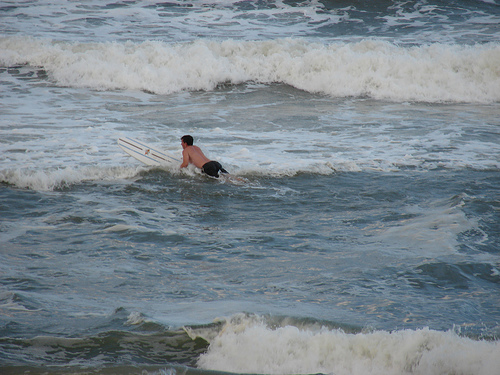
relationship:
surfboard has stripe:
[115, 135, 184, 166] [120, 144, 193, 175]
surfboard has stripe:
[115, 135, 184, 166] [116, 136, 183, 166]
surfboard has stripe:
[115, 135, 184, 166] [126, 131, 179, 161]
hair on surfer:
[175, 128, 196, 147] [178, 134, 231, 179]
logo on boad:
[146, 147, 151, 159] [114, 138, 183, 168]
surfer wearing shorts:
[178, 134, 231, 179] [203, 156, 226, 176]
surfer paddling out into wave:
[176, 132, 245, 191] [7, 297, 498, 374]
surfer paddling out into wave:
[176, 132, 245, 191] [4, 147, 499, 216]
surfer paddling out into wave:
[176, 132, 245, 191] [1, 21, 498, 116]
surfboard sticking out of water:
[115, 135, 184, 166] [2, 1, 499, 373]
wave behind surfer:
[55, 21, 484, 138] [166, 133, 269, 229]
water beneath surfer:
[2, 1, 499, 373] [180, 134, 247, 184]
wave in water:
[0, 145, 499, 199] [2, 1, 499, 373]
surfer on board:
[178, 134, 231, 179] [117, 135, 205, 175]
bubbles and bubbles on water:
[194, 312, 499, 374] [0, 0, 500, 375]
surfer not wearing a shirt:
[178, 134, 231, 179] [180, 117, 244, 214]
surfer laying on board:
[178, 134, 231, 179] [91, 123, 179, 173]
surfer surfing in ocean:
[178, 134, 231, 179] [0, 0, 500, 373]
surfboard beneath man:
[112, 130, 184, 167] [173, 133, 241, 184]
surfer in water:
[178, 134, 231, 179] [2, 1, 499, 373]